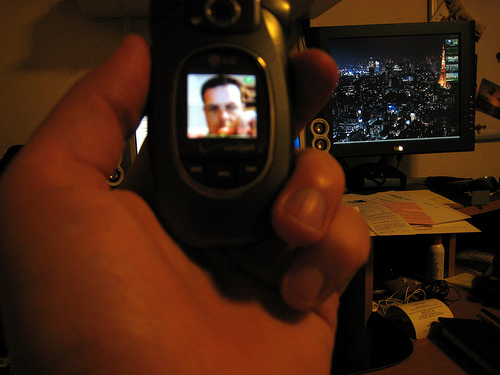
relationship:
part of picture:
[189, 75, 255, 136] [190, 72, 258, 139]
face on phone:
[205, 80, 242, 135] [150, 9, 300, 246]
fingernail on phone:
[277, 187, 334, 229] [150, 9, 300, 246]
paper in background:
[378, 200, 434, 225] [309, 20, 499, 364]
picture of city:
[303, 41, 454, 137] [339, 57, 456, 132]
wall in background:
[0, 5, 129, 95] [309, 20, 499, 364]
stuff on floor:
[372, 257, 499, 371] [341, 291, 498, 372]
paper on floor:
[389, 288, 450, 339] [341, 291, 498, 372]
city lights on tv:
[339, 57, 456, 132] [278, 23, 482, 155]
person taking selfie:
[19, 101, 333, 375] [190, 72, 258, 139]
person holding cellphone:
[19, 101, 333, 375] [150, 9, 300, 246]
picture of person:
[190, 72, 258, 139] [19, 101, 333, 375]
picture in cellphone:
[190, 72, 258, 139] [150, 9, 300, 246]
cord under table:
[377, 298, 403, 308] [338, 208, 474, 294]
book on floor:
[389, 288, 450, 339] [341, 291, 498, 372]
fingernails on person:
[277, 184, 331, 310] [19, 101, 333, 375]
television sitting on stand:
[278, 23, 482, 155] [338, 208, 474, 294]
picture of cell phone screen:
[190, 72, 258, 139] [179, 52, 275, 203]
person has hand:
[19, 101, 333, 375] [0, 33, 366, 375]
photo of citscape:
[278, 23, 482, 155] [303, 41, 454, 137]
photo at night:
[278, 23, 482, 155] [333, 39, 425, 72]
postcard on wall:
[474, 76, 500, 102] [0, 5, 129, 95]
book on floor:
[432, 307, 499, 364] [341, 291, 498, 372]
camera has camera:
[201, 3, 254, 34] [205, 3, 240, 27]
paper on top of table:
[378, 200, 434, 225] [338, 208, 474, 294]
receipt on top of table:
[363, 202, 402, 242] [338, 208, 474, 294]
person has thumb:
[19, 101, 333, 375] [23, 25, 172, 220]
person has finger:
[19, 101, 333, 375] [284, 151, 339, 247]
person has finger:
[19, 101, 333, 375] [279, 199, 365, 316]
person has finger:
[19, 101, 333, 375] [285, 52, 341, 132]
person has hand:
[19, 101, 333, 375] [19, 10, 348, 368]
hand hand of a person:
[0, 33, 366, 375] [19, 101, 333, 375]